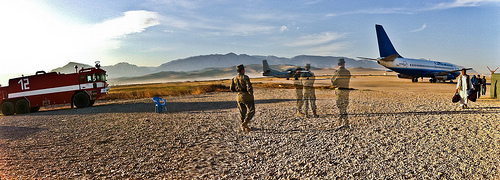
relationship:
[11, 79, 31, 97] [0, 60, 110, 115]
number on fire truck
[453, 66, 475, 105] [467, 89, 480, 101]
man carrying bag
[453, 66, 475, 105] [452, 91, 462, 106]
man carrying bag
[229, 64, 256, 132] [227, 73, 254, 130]
jumpsuit in jumpsuit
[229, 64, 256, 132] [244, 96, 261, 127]
jumpsuit with leg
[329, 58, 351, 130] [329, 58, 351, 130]
ghost soldiers in ghost soldiers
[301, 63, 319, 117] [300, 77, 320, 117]
jumpsuit in jumpsuit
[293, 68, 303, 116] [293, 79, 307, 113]
jumpsuit in jumpsuit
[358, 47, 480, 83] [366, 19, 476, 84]
white body of airplane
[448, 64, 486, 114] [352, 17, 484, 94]
people walking to airplane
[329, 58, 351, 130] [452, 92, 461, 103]
ghost soldiers carrying suitcase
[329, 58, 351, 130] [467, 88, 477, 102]
ghost soldiers carrying bag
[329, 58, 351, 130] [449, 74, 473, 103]
ghost soldiers wearing thawb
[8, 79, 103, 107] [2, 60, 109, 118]
white stripe on fire truck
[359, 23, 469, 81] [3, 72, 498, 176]
airplane on ground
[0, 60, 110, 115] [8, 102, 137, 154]
fire truck on gravel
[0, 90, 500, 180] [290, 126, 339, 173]
gravel on ground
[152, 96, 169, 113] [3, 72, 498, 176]
chair on ground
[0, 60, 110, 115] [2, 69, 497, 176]
fire truck on airstrip